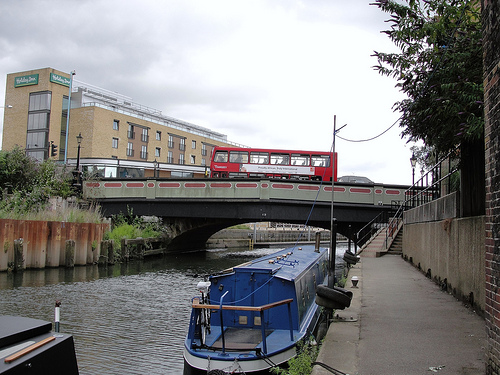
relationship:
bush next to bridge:
[16, 164, 130, 191] [140, 160, 443, 225]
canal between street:
[154, 232, 355, 370] [304, 232, 498, 359]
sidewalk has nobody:
[355, 263, 463, 375] [304, 232, 498, 359]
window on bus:
[269, 146, 341, 169] [183, 112, 388, 194]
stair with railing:
[351, 196, 436, 264] [346, 206, 382, 237]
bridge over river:
[140, 160, 443, 225] [10, 218, 327, 356]